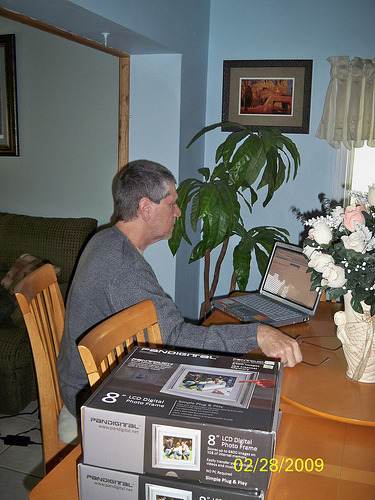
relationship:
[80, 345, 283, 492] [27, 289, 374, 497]
box on top of table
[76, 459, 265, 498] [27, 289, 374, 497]
box on top of table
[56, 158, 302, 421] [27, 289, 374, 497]
man sitting at table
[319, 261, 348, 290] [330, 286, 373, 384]
flower in vase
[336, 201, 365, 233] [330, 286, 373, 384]
flower in vase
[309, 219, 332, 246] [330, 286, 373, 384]
flower in vase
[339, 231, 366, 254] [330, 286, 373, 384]
flower in vase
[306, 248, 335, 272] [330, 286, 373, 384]
flower in vase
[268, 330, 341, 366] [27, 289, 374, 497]
glasses are on table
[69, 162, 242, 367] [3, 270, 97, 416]
man in chair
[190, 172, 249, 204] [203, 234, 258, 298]
leaf on stem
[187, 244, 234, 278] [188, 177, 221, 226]
leaf on stem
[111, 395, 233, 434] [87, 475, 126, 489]
box on box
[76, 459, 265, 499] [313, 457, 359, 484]
box on table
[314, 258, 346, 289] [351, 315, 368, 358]
rose on vase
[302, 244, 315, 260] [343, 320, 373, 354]
rose on vase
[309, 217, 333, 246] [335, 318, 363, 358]
flower on vase